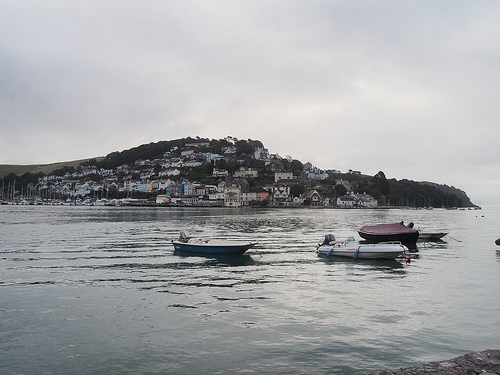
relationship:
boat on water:
[169, 232, 252, 257] [2, 204, 497, 372]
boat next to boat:
[169, 232, 252, 257] [316, 232, 406, 265]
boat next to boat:
[316, 232, 406, 265] [357, 218, 419, 243]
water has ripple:
[2, 204, 497, 372] [7, 272, 253, 290]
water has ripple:
[2, 204, 497, 372] [17, 257, 216, 273]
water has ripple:
[2, 204, 497, 372] [167, 289, 270, 306]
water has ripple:
[2, 204, 497, 372] [346, 263, 393, 272]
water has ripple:
[2, 204, 497, 372] [260, 255, 326, 270]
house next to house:
[212, 167, 228, 178] [237, 165, 258, 178]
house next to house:
[212, 167, 228, 178] [224, 184, 241, 205]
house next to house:
[180, 147, 194, 160] [209, 150, 222, 162]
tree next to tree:
[62, 166, 73, 171] [89, 160, 98, 167]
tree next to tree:
[104, 157, 115, 166] [89, 160, 98, 167]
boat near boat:
[169, 232, 252, 257] [316, 232, 406, 265]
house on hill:
[180, 147, 194, 160] [3, 135, 470, 210]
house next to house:
[209, 150, 222, 162] [212, 167, 228, 178]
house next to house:
[237, 165, 258, 178] [224, 184, 241, 205]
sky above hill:
[0, 2, 499, 202] [3, 135, 470, 210]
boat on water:
[316, 232, 406, 265] [2, 204, 497, 372]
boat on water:
[357, 218, 419, 243] [2, 204, 497, 372]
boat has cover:
[357, 218, 419, 243] [359, 220, 420, 243]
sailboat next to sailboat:
[43, 186, 53, 208] [47, 190, 54, 205]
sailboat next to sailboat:
[63, 192, 71, 205] [47, 190, 54, 205]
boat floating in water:
[169, 232, 252, 257] [2, 204, 497, 372]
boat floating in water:
[316, 232, 406, 265] [2, 204, 497, 372]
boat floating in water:
[357, 218, 419, 243] [2, 204, 497, 372]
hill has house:
[3, 135, 470, 210] [180, 147, 194, 160]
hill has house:
[3, 135, 470, 210] [209, 150, 222, 162]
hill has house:
[3, 135, 470, 210] [212, 167, 228, 178]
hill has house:
[3, 135, 470, 210] [237, 165, 258, 178]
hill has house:
[3, 135, 470, 210] [224, 184, 241, 205]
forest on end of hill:
[364, 170, 457, 209] [350, 168, 476, 209]